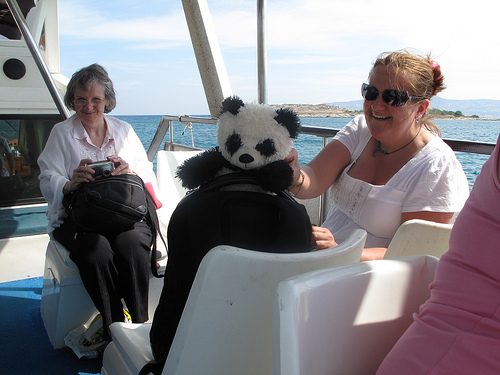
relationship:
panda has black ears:
[174, 95, 301, 197] [219, 93, 302, 138]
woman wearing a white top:
[283, 52, 473, 260] [312, 115, 470, 257]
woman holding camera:
[37, 62, 162, 344] [83, 159, 116, 181]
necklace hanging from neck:
[373, 120, 427, 158] [369, 115, 427, 157]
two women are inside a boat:
[36, 49, 473, 350] [1, 2, 500, 375]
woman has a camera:
[37, 62, 162, 344] [83, 159, 116, 181]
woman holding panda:
[283, 52, 473, 260] [174, 95, 301, 197]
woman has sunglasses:
[283, 52, 473, 260] [360, 82, 431, 108]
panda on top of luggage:
[174, 95, 301, 197] [148, 172, 314, 373]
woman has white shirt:
[37, 62, 162, 344] [37, 113, 157, 235]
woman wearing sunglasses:
[283, 52, 473, 260] [360, 82, 431, 108]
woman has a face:
[37, 62, 162, 344] [72, 84, 105, 127]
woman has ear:
[283, 52, 473, 260] [413, 98, 429, 124]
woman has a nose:
[37, 62, 162, 344] [238, 153, 255, 166]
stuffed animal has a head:
[174, 95, 301, 197] [216, 97, 302, 171]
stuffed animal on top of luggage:
[174, 95, 301, 197] [148, 172, 314, 373]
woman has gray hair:
[37, 62, 162, 344] [64, 63, 117, 114]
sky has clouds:
[59, 2, 500, 114] [64, 8, 498, 59]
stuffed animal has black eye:
[174, 95, 301, 197] [223, 132, 277, 158]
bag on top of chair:
[148, 172, 314, 373] [98, 228, 373, 374]